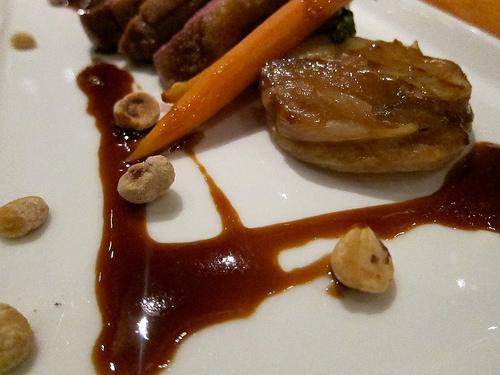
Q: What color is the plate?
A: White.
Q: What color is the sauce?
A: Brown.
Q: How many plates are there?
A: One.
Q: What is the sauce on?
A: The plate.